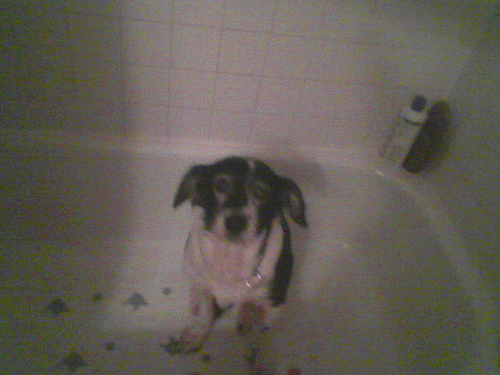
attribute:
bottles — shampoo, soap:
[372, 87, 429, 182]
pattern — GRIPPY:
[45, 282, 285, 367]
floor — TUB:
[16, 219, 361, 359]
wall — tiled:
[8, 6, 497, 155]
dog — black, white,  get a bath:
[157, 143, 313, 373]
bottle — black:
[402, 94, 458, 179]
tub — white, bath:
[6, 132, 498, 362]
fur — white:
[193, 248, 247, 295]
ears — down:
[166, 157, 313, 233]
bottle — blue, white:
[377, 84, 433, 176]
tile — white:
[76, 20, 382, 133]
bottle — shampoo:
[377, 86, 438, 186]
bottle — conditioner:
[418, 90, 455, 190]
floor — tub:
[22, 246, 187, 369]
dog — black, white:
[166, 146, 306, 363]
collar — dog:
[231, 230, 278, 299]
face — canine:
[200, 165, 268, 245]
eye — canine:
[215, 178, 229, 197]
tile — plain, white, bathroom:
[52, 7, 154, 47]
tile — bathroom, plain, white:
[114, 3, 172, 30]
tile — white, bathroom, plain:
[57, 6, 133, 66]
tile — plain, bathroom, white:
[123, 12, 177, 73]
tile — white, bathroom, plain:
[207, 20, 276, 81]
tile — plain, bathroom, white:
[257, 25, 310, 85]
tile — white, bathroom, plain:
[300, 31, 373, 101]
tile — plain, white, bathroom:
[321, 25, 416, 105]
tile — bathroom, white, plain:
[166, 90, 221, 145]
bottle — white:
[372, 90, 428, 178]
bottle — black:
[393, 100, 453, 178]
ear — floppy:
[277, 169, 313, 232]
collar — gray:
[219, 227, 271, 288]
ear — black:
[275, 172, 311, 233]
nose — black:
[220, 211, 250, 236]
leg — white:
[159, 283, 214, 361]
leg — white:
[237, 296, 288, 373]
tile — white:
[5, 2, 272, 142]